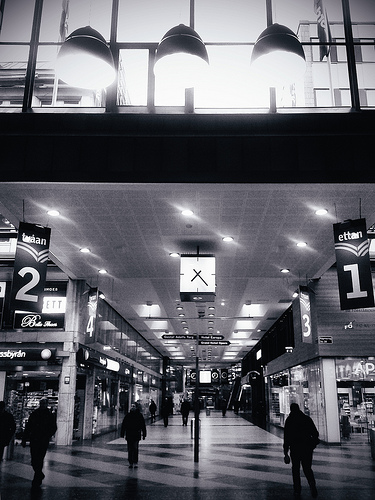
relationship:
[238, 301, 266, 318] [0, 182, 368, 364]
square lights in ceiling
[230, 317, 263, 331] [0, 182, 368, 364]
square lights in ceiling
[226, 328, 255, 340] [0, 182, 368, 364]
square lights in ceiling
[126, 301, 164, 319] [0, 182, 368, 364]
square lights in ceiling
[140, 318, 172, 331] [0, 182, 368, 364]
square lights in ceiling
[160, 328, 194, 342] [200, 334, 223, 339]
sign has lettering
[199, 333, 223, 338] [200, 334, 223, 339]
sign has lettering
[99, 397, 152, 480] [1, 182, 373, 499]
person shopping in mall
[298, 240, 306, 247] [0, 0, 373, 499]
light in mall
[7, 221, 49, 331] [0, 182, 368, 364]
banners hanging from ceiling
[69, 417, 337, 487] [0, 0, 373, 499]
walkway in mall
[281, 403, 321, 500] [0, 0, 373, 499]
person walking inside mall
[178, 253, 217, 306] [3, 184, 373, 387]
clock hanging down from ceiling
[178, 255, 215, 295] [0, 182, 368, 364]
clock from ceiling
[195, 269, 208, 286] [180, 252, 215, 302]
hand on clock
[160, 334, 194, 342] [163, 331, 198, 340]
sign with writing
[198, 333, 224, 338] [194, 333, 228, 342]
sign with writing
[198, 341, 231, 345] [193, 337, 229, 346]
sign with writing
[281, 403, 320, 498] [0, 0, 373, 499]
person shopping in mall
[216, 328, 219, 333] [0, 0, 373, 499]
light in mall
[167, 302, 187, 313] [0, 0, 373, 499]
overhead light in mall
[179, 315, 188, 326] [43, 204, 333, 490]
light in mall